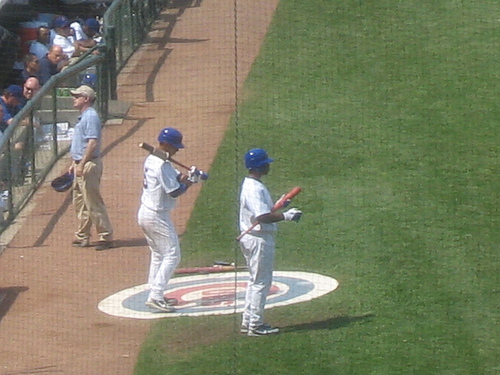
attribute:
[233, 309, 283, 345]
footwear — black and white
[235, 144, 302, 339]
man — sports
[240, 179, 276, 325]
uniform — white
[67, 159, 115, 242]
pants — khaki 